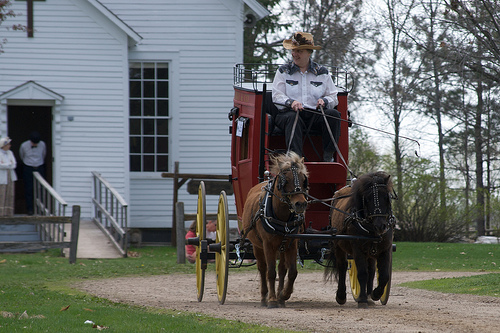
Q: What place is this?
A: It is a church.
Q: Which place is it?
A: It is a church.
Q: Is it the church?
A: Yes, it is the church.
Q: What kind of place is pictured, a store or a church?
A: It is a church.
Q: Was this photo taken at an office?
A: No, the picture was taken in a church.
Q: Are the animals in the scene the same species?
A: Yes, all the animals are horses.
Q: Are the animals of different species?
A: No, all the animals are horses.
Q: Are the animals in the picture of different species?
A: No, all the animals are horses.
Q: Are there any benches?
A: No, there are no benches.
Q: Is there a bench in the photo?
A: No, there are no benches.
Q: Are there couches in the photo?
A: Yes, there is a couch.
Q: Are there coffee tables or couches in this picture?
A: Yes, there is a couch.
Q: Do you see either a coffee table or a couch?
A: Yes, there is a couch.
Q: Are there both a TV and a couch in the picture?
A: No, there is a couch but no televisions.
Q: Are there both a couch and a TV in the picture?
A: No, there is a couch but no televisions.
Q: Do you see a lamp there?
A: No, there are no lamps.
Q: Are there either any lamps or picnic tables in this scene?
A: No, there are no lamps or picnic tables.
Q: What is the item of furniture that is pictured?
A: The piece of furniture is a couch.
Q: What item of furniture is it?
A: The piece of furniture is a couch.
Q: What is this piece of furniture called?
A: This is a couch.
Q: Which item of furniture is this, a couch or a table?
A: This is a couch.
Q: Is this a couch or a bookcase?
A: This is a couch.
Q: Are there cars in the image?
A: No, there are no cars.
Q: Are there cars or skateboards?
A: No, there are no cars or skateboards.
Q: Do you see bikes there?
A: No, there are no bikes.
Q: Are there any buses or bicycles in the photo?
A: No, there are no bicycles or buses.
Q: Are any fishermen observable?
A: No, there are no fishermen.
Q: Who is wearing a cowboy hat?
A: The man is wearing a cowboy hat.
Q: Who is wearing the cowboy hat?
A: The man is wearing a cowboy hat.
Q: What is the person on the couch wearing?
A: The man is wearing a cowboy hat.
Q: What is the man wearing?
A: The man is wearing a cowboy hat.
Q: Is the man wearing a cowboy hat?
A: Yes, the man is wearing a cowboy hat.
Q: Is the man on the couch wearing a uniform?
A: No, the man is wearing a cowboy hat.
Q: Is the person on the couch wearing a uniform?
A: No, the man is wearing a cowboy hat.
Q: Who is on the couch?
A: The man is on the couch.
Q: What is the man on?
A: The man is on the couch.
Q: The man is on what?
A: The man is on the couch.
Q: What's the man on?
A: The man is on the couch.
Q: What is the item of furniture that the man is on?
A: The piece of furniture is a couch.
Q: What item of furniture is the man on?
A: The man is on the couch.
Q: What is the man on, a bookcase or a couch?
A: The man is on a couch.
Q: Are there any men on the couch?
A: Yes, there is a man on the couch.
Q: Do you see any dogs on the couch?
A: No, there is a man on the couch.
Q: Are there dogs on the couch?
A: No, there is a man on the couch.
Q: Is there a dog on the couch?
A: No, there is a man on the couch.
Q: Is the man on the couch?
A: Yes, the man is on the couch.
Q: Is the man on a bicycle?
A: No, the man is on the couch.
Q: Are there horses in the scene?
A: Yes, there is a horse.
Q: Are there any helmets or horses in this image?
A: Yes, there is a horse.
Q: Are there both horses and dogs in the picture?
A: No, there is a horse but no dogs.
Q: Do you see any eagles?
A: No, there are no eagles.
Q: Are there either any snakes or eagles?
A: No, there are no eagles or snakes.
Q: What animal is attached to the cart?
A: The horse is attached to the cart.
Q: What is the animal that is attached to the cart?
A: The animal is a horse.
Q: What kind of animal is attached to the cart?
A: The animal is a horse.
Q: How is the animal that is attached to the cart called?
A: The animal is a horse.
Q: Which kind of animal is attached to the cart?
A: The animal is a horse.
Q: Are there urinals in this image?
A: No, there are no urinals.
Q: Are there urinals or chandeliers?
A: No, there are no urinals or chandeliers.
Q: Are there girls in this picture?
A: No, there are no girls.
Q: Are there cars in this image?
A: No, there are no cars.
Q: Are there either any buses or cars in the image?
A: No, there are no cars or buses.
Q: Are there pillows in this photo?
A: No, there are no pillows.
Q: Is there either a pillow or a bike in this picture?
A: No, there are no pillows or bikes.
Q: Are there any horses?
A: Yes, there is a horse.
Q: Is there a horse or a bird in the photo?
A: Yes, there is a horse.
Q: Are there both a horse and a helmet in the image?
A: No, there is a horse but no helmets.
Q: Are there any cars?
A: No, there are no cars.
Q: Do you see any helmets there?
A: No, there are no helmets.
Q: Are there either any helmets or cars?
A: No, there are no helmets or cars.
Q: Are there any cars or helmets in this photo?
A: No, there are no helmets or cars.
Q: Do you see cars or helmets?
A: No, there are no helmets or cars.